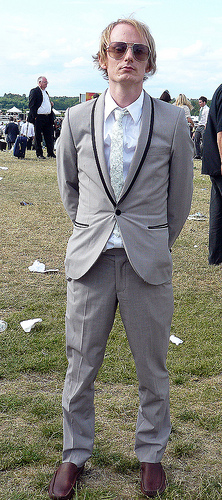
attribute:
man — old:
[28, 74, 70, 153]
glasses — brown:
[110, 44, 151, 63]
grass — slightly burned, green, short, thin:
[1, 148, 220, 496]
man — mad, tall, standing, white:
[47, 11, 194, 498]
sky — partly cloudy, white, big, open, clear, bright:
[2, 2, 220, 88]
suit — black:
[25, 68, 56, 156]